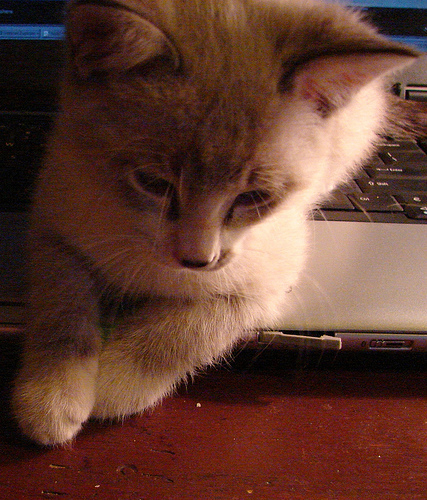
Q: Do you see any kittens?
A: Yes, there is a kitten.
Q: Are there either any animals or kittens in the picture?
A: Yes, there is a kitten.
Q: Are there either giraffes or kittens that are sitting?
A: Yes, the kitten is sitting.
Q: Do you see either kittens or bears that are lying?
A: Yes, the kitten is lying.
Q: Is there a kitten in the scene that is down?
A: Yes, there is a kitten that is down.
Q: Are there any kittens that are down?
A: Yes, there is a kitten that is down.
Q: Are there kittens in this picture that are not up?
A: Yes, there is a kitten that is down.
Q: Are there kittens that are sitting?
A: Yes, there is a kitten that is sitting.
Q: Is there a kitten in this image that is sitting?
A: Yes, there is a kitten that is sitting.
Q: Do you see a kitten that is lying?
A: Yes, there is a kitten that is lying.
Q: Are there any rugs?
A: No, there are no rugs.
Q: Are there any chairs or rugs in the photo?
A: No, there are no rugs or chairs.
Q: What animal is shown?
A: The animal is a kitten.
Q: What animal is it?
A: The animal is a kitten.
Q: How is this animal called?
A: This is a kitten.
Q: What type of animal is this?
A: This is a kitten.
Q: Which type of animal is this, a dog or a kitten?
A: This is a kitten.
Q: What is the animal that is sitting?
A: The animal is a kitten.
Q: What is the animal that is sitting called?
A: The animal is a kitten.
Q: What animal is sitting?
A: The animal is a kitten.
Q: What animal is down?
A: The animal is a kitten.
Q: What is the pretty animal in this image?
A: The animal is a kitten.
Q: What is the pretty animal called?
A: The animal is a kitten.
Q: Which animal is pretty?
A: The animal is a kitten.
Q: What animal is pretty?
A: The animal is a kitten.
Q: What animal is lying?
A: The animal is a kitten.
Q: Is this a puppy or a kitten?
A: This is a kitten.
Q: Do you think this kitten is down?
A: Yes, the kitten is down.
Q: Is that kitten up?
A: No, the kitten is down.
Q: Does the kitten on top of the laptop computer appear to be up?
A: No, the kitten is down.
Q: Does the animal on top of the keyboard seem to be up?
A: No, the kitten is down.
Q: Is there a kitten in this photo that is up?
A: No, there is a kitten but it is down.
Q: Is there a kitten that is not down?
A: No, there is a kitten but it is down.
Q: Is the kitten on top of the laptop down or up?
A: The kitten is down.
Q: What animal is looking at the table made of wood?
A: The kitten is looking at the table.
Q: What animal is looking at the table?
A: The kitten is looking at the table.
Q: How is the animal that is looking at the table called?
A: The animal is a kitten.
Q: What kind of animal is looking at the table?
A: The animal is a kitten.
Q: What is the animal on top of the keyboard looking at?
A: The kitten is looking at the table.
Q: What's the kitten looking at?
A: The kitten is looking at the table.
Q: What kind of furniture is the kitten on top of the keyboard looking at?
A: The kitten is looking at the table.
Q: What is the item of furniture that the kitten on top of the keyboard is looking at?
A: The piece of furniture is a table.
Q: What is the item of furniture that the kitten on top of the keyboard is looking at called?
A: The piece of furniture is a table.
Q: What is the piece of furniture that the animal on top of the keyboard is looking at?
A: The piece of furniture is a table.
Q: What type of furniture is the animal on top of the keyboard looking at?
A: The kitten is looking at the table.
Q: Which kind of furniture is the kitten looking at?
A: The kitten is looking at the table.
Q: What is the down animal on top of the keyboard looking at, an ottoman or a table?
A: The kitten is looking at a table.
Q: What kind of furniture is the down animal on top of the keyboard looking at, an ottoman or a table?
A: The kitten is looking at a table.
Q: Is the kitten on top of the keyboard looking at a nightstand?
A: No, the kitten is looking at a table.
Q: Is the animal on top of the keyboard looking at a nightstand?
A: No, the kitten is looking at a table.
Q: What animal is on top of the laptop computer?
A: The kitten is on top of the laptop computer.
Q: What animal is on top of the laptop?
A: The kitten is on top of the laptop computer.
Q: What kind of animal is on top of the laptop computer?
A: The animal is a kitten.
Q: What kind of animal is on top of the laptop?
A: The animal is a kitten.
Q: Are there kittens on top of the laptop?
A: Yes, there is a kitten on top of the laptop.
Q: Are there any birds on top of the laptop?
A: No, there is a kitten on top of the laptop.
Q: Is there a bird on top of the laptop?
A: No, there is a kitten on top of the laptop.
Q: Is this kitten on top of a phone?
A: No, the kitten is on top of the laptop.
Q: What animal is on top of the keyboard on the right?
A: The kitten is on top of the keyboard.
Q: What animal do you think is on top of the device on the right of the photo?
A: The kitten is on top of the keyboard.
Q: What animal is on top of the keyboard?
A: The kitten is on top of the keyboard.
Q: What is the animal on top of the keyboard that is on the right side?
A: The animal is a kitten.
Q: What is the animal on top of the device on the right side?
A: The animal is a kitten.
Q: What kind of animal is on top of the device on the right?
A: The animal is a kitten.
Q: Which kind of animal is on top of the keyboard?
A: The animal is a kitten.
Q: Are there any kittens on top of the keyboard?
A: Yes, there is a kitten on top of the keyboard.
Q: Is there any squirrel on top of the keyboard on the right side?
A: No, there is a kitten on top of the keyboard.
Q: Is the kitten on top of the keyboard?
A: Yes, the kitten is on top of the keyboard.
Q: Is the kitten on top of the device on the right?
A: Yes, the kitten is on top of the keyboard.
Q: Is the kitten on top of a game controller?
A: No, the kitten is on top of the keyboard.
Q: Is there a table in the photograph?
A: Yes, there is a table.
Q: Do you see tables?
A: Yes, there is a table.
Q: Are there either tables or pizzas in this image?
A: Yes, there is a table.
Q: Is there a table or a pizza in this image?
A: Yes, there is a table.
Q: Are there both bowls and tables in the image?
A: No, there is a table but no bowls.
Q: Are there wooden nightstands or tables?
A: Yes, there is a wood table.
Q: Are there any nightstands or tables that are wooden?
A: Yes, the table is wooden.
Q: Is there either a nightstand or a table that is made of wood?
A: Yes, the table is made of wood.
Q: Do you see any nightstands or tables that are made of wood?
A: Yes, the table is made of wood.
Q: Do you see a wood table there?
A: Yes, there is a wood table.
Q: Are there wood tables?
A: Yes, there is a wood table.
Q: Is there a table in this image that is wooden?
A: Yes, there is a table that is wooden.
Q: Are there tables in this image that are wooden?
A: Yes, there is a table that is wooden.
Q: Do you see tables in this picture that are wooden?
A: Yes, there is a table that is wooden.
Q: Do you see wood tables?
A: Yes, there is a table that is made of wood.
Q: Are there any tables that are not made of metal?
A: Yes, there is a table that is made of wood.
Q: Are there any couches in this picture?
A: No, there are no couches.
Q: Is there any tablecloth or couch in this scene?
A: No, there are no couches or tablecloths.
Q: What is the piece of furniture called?
A: The piece of furniture is a table.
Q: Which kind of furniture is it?
A: The piece of furniture is a table.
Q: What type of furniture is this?
A: This is a table.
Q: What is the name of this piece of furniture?
A: This is a table.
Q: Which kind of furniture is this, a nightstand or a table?
A: This is a table.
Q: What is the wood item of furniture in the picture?
A: The piece of furniture is a table.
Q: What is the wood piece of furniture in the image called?
A: The piece of furniture is a table.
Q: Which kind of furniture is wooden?
A: The furniture is a table.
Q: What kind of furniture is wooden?
A: The furniture is a table.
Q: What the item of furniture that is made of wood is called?
A: The piece of furniture is a table.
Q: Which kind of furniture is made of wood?
A: The furniture is a table.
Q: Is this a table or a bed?
A: This is a table.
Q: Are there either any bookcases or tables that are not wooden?
A: No, there is a table but it is wooden.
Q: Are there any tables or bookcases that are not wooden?
A: No, there is a table but it is wooden.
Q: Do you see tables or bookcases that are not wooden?
A: No, there is a table but it is wooden.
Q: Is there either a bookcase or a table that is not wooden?
A: No, there is a table but it is wooden.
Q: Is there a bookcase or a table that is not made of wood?
A: No, there is a table but it is made of wood.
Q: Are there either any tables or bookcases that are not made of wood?
A: No, there is a table but it is made of wood.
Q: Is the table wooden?
A: Yes, the table is wooden.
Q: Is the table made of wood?
A: Yes, the table is made of wood.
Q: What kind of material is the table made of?
A: The table is made of wood.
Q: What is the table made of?
A: The table is made of wood.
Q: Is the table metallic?
A: No, the table is wooden.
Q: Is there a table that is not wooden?
A: No, there is a table but it is wooden.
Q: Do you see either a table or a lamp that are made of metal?
A: No, there is a table but it is made of wood.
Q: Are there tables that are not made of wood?
A: No, there is a table but it is made of wood.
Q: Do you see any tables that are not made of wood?
A: No, there is a table but it is made of wood.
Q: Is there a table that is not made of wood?
A: No, there is a table but it is made of wood.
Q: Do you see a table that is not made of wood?
A: No, there is a table but it is made of wood.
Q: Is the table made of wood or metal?
A: The table is made of wood.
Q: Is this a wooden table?
A: Yes, this is a wooden table.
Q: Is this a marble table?
A: No, this is a wooden table.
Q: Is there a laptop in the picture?
A: Yes, there is a laptop.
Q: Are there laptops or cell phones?
A: Yes, there is a laptop.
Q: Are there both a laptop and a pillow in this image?
A: No, there is a laptop but no pillows.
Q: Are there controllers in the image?
A: No, there are no controllers.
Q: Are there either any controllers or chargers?
A: No, there are no controllers or chargers.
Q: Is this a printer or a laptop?
A: This is a laptop.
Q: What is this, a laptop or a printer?
A: This is a laptop.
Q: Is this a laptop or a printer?
A: This is a laptop.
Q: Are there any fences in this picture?
A: No, there are no fences.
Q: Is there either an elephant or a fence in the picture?
A: No, there are no fences or elephants.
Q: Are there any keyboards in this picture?
A: Yes, there is a keyboard.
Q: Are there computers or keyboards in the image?
A: Yes, there is a keyboard.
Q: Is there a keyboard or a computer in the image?
A: Yes, there is a keyboard.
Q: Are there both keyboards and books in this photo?
A: No, there is a keyboard but no books.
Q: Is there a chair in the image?
A: No, there are no chairs.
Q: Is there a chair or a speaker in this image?
A: No, there are no chairs or speakers.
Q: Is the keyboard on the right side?
A: Yes, the keyboard is on the right of the image.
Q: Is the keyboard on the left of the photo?
A: No, the keyboard is on the right of the image.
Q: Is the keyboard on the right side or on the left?
A: The keyboard is on the right of the image.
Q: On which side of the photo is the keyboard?
A: The keyboard is on the right of the image.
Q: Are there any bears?
A: No, there are no bears.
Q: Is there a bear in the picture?
A: No, there are no bears.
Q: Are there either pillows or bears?
A: No, there are no bears or pillows.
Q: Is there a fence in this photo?
A: No, there are no fences.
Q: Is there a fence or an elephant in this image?
A: No, there are no fences or elephants.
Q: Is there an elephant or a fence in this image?
A: No, there are no fences or elephants.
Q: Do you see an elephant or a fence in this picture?
A: No, there are no fences or elephants.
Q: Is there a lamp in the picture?
A: No, there are no lamps.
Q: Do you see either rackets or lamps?
A: No, there are no lamps or rackets.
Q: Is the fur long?
A: Yes, the fur is long.